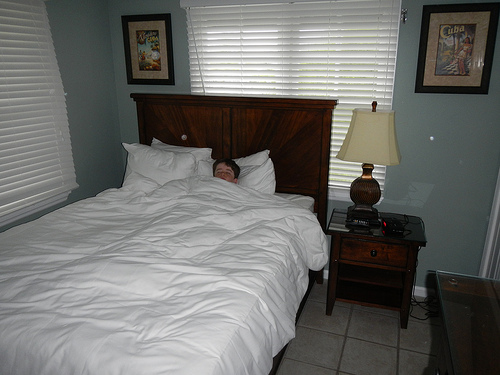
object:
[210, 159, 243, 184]
boy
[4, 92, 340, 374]
bed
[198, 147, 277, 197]
pillow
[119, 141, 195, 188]
pillow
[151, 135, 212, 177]
pillow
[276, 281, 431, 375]
floor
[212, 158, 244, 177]
hair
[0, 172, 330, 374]
bed cover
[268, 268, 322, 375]
frame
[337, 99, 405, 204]
lamp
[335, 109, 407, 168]
lampshade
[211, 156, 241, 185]
head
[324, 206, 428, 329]
table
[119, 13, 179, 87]
picture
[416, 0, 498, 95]
picture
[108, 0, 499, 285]
wall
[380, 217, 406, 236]
alarm clock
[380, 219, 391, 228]
numbers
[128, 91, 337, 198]
headboard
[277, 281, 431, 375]
tile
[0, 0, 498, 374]
picture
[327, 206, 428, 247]
top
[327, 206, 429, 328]
nightstand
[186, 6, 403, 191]
window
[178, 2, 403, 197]
mini blinds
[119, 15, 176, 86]
frame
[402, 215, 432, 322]
cord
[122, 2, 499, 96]
pictures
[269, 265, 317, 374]
bed frame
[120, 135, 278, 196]
pillows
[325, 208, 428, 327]
dresser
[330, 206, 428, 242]
protective layer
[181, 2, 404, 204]
shade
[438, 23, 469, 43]
cuba